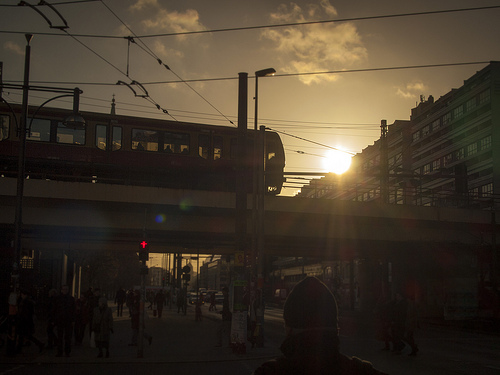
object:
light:
[252, 66, 276, 81]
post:
[247, 71, 270, 163]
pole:
[219, 228, 262, 357]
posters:
[228, 275, 250, 313]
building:
[385, 64, 497, 365]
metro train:
[1, 102, 288, 198]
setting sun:
[318, 142, 353, 177]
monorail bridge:
[4, 164, 484, 255]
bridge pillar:
[230, 241, 275, 355]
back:
[256, 277, 376, 373]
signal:
[135, 230, 152, 264]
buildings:
[304, 124, 410, 319]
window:
[155, 130, 174, 156]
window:
[133, 132, 160, 161]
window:
[113, 128, 129, 157]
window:
[88, 123, 108, 155]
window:
[52, 126, 79, 149]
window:
[178, 133, 195, 154]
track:
[13, 174, 494, 299]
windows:
[211, 131, 224, 161]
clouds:
[387, 75, 433, 102]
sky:
[201, 8, 274, 61]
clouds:
[117, 4, 196, 53]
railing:
[19, 19, 110, 91]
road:
[184, 294, 393, 374]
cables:
[40, 30, 432, 86]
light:
[139, 239, 148, 249]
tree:
[53, 224, 104, 306]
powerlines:
[274, 120, 381, 189]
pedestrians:
[121, 257, 206, 323]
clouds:
[278, 25, 355, 85]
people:
[350, 243, 449, 363]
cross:
[133, 230, 157, 261]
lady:
[86, 296, 115, 374]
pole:
[229, 66, 252, 354]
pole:
[252, 65, 268, 358]